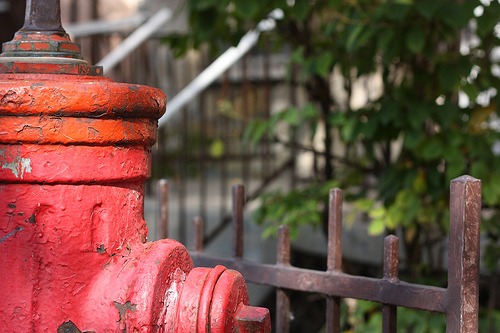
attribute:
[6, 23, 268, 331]
paint — red, cracked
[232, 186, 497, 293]
gate — iron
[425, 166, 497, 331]
bar — rusty, metal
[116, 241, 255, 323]
outlet — water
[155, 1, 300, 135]
rail — white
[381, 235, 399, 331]
metal bar — rusty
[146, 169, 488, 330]
gate — iron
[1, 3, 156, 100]
spot — silver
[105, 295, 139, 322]
paint — chipped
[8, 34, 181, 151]
top — orange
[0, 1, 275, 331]
hydrant — red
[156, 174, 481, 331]
fence — iron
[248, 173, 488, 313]
fence — old, metal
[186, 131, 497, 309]
bar — metal, rusty